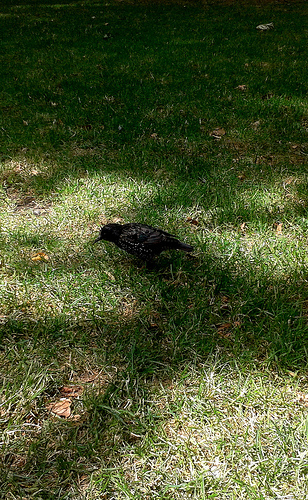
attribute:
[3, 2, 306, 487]
grass — large, green, patchy, daytime, shaded, field, stalks, deep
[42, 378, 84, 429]
leaf — brown, yellow, dead, scattered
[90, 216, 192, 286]
bird — small, standing, black, raven, crow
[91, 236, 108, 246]
beak — black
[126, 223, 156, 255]
feathers — spotted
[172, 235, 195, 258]
feathers — tail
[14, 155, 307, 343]
sunlight — shining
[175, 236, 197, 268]
tail — feathers